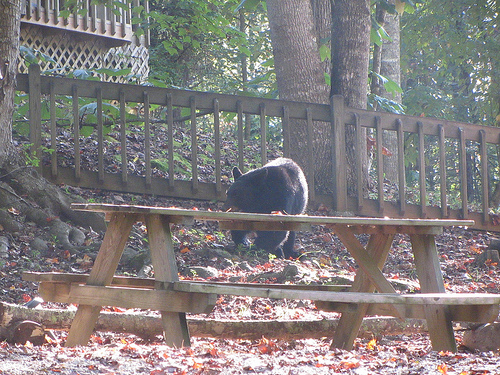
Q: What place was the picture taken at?
A: It was taken at the park.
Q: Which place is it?
A: It is a park.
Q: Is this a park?
A: Yes, it is a park.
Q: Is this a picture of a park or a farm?
A: It is showing a park.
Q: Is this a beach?
A: No, it is a park.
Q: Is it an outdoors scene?
A: Yes, it is outdoors.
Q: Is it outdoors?
A: Yes, it is outdoors.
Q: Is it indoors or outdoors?
A: It is outdoors.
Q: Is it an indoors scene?
A: No, it is outdoors.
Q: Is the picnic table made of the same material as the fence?
A: Yes, both the picnic table and the fence are made of wood.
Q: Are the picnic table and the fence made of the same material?
A: Yes, both the picnic table and the fence are made of wood.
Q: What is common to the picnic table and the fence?
A: The material, both the picnic table and the fence are wooden.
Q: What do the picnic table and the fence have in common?
A: The material, both the picnic table and the fence are wooden.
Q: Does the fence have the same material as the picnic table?
A: Yes, both the fence and the picnic table are made of wood.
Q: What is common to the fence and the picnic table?
A: The material, both the fence and the picnic table are wooden.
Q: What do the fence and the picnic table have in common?
A: The material, both the fence and the picnic table are wooden.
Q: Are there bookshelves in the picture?
A: No, there are no bookshelves.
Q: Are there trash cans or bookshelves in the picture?
A: No, there are no bookshelves or trash cans.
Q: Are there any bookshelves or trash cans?
A: No, there are no bookshelves or trash cans.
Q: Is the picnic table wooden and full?
A: No, the picnic table is wooden but empty.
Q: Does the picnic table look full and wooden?
A: No, the picnic table is wooden but empty.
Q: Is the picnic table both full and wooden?
A: No, the picnic table is wooden but empty.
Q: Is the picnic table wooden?
A: Yes, the picnic table is wooden.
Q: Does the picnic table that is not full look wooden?
A: Yes, the picnic table is wooden.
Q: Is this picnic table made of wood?
A: Yes, the picnic table is made of wood.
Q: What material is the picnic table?
A: The picnic table is made of wood.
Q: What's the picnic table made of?
A: The picnic table is made of wood.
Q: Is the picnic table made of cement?
A: No, the picnic table is made of wood.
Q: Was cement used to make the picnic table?
A: No, the picnic table is made of wood.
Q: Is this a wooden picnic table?
A: Yes, this is a wooden picnic table.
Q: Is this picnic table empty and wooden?
A: Yes, the picnic table is empty and wooden.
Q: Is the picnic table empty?
A: Yes, the picnic table is empty.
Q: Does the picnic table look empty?
A: Yes, the picnic table is empty.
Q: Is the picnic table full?
A: No, the picnic table is empty.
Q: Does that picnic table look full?
A: No, the picnic table is empty.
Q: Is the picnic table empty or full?
A: The picnic table is empty.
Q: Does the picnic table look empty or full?
A: The picnic table is empty.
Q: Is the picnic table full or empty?
A: The picnic table is empty.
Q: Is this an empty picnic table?
A: Yes, this is an empty picnic table.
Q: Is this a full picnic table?
A: No, this is an empty picnic table.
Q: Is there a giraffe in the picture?
A: No, there are no giraffes.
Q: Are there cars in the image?
A: No, there are no cars.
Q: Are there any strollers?
A: No, there are no strollers.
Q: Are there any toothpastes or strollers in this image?
A: No, there are no strollers or toothpastes.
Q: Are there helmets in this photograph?
A: No, there are no helmets.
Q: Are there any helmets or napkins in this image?
A: No, there are no helmets or napkins.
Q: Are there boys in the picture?
A: No, there are no boys.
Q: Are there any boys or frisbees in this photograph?
A: No, there are no boys or frisbees.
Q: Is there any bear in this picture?
A: Yes, there is a bear.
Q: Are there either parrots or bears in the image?
A: Yes, there is a bear.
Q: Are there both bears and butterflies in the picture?
A: No, there is a bear but no butterflies.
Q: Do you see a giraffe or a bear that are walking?
A: Yes, the bear is walking.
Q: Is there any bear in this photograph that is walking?
A: Yes, there is a bear that is walking.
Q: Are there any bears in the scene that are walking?
A: Yes, there is a bear that is walking.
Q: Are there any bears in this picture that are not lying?
A: Yes, there is a bear that is walking.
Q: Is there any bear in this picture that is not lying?
A: Yes, there is a bear that is walking.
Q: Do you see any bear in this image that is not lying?
A: Yes, there is a bear that is walking .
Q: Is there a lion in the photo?
A: No, there are no lions.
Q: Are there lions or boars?
A: No, there are no lions or boars.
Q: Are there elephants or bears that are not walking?
A: No, there is a bear but it is walking.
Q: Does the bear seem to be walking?
A: Yes, the bear is walking.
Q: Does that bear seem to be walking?
A: Yes, the bear is walking.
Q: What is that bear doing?
A: The bear is walking.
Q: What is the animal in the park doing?
A: The bear is walking.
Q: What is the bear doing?
A: The bear is walking.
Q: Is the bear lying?
A: No, the bear is walking.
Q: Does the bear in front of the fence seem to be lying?
A: No, the bear is walking.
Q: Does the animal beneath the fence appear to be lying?
A: No, the bear is walking.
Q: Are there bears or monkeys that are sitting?
A: No, there is a bear but it is walking.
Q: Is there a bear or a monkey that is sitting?
A: No, there is a bear but it is walking.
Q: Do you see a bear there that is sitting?
A: No, there is a bear but it is walking.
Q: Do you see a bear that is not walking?
A: No, there is a bear but it is walking.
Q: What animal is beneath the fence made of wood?
A: The bear is beneath the fence.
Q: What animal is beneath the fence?
A: The bear is beneath the fence.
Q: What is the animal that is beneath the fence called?
A: The animal is a bear.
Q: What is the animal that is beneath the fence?
A: The animal is a bear.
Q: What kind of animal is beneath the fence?
A: The animal is a bear.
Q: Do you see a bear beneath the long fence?
A: Yes, there is a bear beneath the fence.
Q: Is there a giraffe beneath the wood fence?
A: No, there is a bear beneath the fence.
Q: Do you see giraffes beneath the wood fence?
A: No, there is a bear beneath the fence.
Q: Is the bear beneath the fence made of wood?
A: Yes, the bear is beneath the fence.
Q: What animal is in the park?
A: The animal is a bear.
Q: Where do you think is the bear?
A: The bear is in the park.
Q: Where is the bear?
A: The bear is in the park.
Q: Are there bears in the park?
A: Yes, there is a bear in the park.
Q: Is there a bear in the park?
A: Yes, there is a bear in the park.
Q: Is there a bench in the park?
A: No, there is a bear in the park.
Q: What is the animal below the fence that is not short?
A: The animal is a bear.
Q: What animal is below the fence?
A: The animal is a bear.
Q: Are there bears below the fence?
A: Yes, there is a bear below the fence.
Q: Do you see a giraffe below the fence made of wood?
A: No, there is a bear below the fence.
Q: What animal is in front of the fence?
A: The bear is in front of the fence.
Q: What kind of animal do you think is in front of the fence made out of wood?
A: The animal is a bear.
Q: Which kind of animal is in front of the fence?
A: The animal is a bear.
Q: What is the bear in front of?
A: The bear is in front of the fence.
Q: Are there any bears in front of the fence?
A: Yes, there is a bear in front of the fence.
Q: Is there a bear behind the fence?
A: No, the bear is in front of the fence.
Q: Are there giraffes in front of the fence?
A: No, there is a bear in front of the fence.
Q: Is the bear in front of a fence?
A: Yes, the bear is in front of a fence.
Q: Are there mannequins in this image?
A: No, there are no mannequins.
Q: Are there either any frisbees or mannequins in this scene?
A: No, there are no mannequins or frisbees.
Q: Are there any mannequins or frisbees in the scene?
A: No, there are no mannequins or frisbees.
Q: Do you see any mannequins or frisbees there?
A: No, there are no mannequins or frisbees.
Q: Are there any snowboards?
A: No, there are no snowboards.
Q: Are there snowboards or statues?
A: No, there are no snowboards or statues.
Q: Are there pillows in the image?
A: No, there are no pillows.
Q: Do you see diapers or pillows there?
A: No, there are no pillows or diapers.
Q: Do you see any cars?
A: No, there are no cars.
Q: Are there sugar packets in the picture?
A: No, there are no sugar packets.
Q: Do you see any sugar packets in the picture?
A: No, there are no sugar packets.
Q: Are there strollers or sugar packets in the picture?
A: No, there are no sugar packets or strollers.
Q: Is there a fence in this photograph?
A: Yes, there is a fence.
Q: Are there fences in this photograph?
A: Yes, there is a fence.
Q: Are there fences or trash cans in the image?
A: Yes, there is a fence.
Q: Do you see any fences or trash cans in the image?
A: Yes, there is a fence.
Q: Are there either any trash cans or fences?
A: Yes, there is a fence.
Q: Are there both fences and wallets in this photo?
A: No, there is a fence but no wallets.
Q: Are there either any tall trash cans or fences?
A: Yes, there is a tall fence.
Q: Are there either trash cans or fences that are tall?
A: Yes, the fence is tall.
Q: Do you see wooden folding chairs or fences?
A: Yes, there is a wood fence.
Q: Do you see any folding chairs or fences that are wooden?
A: Yes, the fence is wooden.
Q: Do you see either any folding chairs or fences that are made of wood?
A: Yes, the fence is made of wood.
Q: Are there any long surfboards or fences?
A: Yes, there is a long fence.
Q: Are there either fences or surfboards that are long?
A: Yes, the fence is long.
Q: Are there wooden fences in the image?
A: Yes, there is a wood fence.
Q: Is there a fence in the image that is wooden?
A: Yes, there is a fence that is wooden.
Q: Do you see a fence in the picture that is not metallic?
A: Yes, there is a wooden fence.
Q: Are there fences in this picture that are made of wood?
A: Yes, there is a fence that is made of wood.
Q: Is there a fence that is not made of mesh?
A: Yes, there is a fence that is made of wood.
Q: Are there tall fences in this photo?
A: Yes, there is a tall fence.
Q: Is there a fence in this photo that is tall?
A: Yes, there is a fence that is tall.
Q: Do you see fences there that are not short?
A: Yes, there is a tall fence.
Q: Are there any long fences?
A: Yes, there is a long fence.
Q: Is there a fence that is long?
A: Yes, there is a fence that is long.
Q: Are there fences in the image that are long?
A: Yes, there is a fence that is long.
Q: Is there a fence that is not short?
A: Yes, there is a long fence.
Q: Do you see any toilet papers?
A: No, there are no toilet papers.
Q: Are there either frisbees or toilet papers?
A: No, there are no toilet papers or frisbees.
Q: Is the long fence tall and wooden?
A: Yes, the fence is tall and wooden.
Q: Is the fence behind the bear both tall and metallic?
A: No, the fence is tall but wooden.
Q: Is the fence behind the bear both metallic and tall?
A: No, the fence is tall but wooden.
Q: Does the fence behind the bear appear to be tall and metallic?
A: No, the fence is tall but wooden.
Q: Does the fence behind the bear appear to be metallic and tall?
A: No, the fence is tall but wooden.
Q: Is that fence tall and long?
A: Yes, the fence is tall and long.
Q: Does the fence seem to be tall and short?
A: No, the fence is tall but long.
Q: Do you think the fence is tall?
A: Yes, the fence is tall.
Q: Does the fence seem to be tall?
A: Yes, the fence is tall.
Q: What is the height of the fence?
A: The fence is tall.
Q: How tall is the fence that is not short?
A: The fence is tall.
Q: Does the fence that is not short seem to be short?
A: No, the fence is tall.